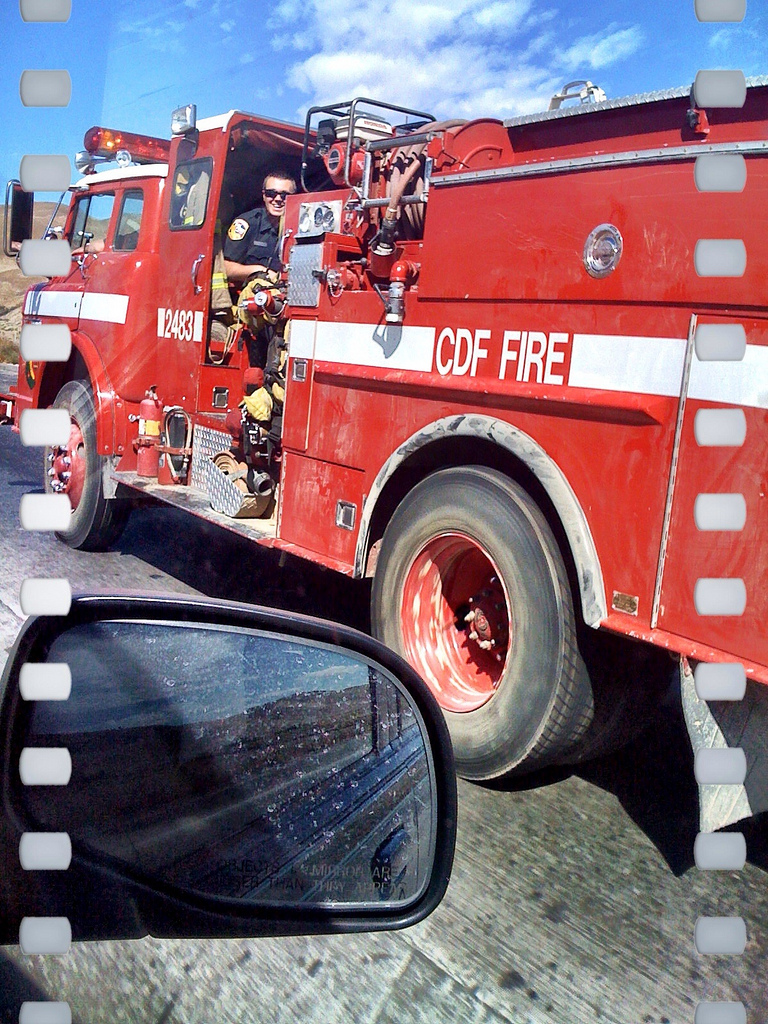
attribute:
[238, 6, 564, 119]
clouds — white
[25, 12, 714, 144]
sky — blue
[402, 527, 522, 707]
rim — red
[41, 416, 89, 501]
rim — red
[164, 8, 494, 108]
sky — blue and white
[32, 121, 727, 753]
firetruck — red and white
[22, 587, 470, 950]
mirror — right side view, sideview, rear view mirror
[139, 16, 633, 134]
clouds — white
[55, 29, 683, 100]
sky — blue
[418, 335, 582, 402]
letters — white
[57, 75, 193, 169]
light — red 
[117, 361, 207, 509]
extinguisher — red , yellow 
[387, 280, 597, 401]
writing — white 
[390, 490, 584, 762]
tire — black 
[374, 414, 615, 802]
tire — black 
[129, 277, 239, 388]
numbers — white 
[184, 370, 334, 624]
kit — Silver 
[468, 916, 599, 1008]
stains — Black 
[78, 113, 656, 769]
truck — red 